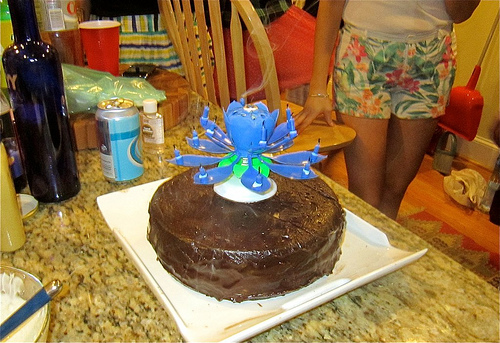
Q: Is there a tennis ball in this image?
A: No, there are no tennis balls.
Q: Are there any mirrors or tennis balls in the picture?
A: No, there are no tennis balls or mirrors.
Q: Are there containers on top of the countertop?
A: Yes, there is a container on top of the countertop.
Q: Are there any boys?
A: No, there are no boys.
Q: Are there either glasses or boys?
A: No, there are no boys or glasses.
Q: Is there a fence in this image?
A: No, there are no fences.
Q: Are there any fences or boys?
A: No, there are no fences or boys.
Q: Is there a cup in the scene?
A: Yes, there is a cup.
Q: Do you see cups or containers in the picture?
A: Yes, there is a cup.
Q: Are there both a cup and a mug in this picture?
A: No, there is a cup but no mugs.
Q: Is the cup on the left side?
A: Yes, the cup is on the left of the image.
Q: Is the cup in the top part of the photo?
A: Yes, the cup is in the top of the image.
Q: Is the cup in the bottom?
A: No, the cup is in the top of the image.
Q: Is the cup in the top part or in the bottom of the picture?
A: The cup is in the top of the image.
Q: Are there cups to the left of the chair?
A: Yes, there is a cup to the left of the chair.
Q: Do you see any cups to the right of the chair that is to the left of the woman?
A: No, the cup is to the left of the chair.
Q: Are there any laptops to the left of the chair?
A: No, there is a cup to the left of the chair.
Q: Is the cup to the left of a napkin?
A: No, the cup is to the left of a chair.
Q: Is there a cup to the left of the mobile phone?
A: Yes, there is a cup to the left of the mobile phone.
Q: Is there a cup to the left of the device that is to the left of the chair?
A: Yes, there is a cup to the left of the mobile phone.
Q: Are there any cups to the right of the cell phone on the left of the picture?
A: No, the cup is to the left of the cell phone.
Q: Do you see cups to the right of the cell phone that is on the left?
A: No, the cup is to the left of the cell phone.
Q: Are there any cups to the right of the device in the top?
A: No, the cup is to the left of the cell phone.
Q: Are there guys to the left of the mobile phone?
A: No, there is a cup to the left of the mobile phone.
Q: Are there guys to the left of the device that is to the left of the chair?
A: No, there is a cup to the left of the mobile phone.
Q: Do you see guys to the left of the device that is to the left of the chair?
A: No, there is a cup to the left of the mobile phone.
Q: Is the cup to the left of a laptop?
A: No, the cup is to the left of a cell phone.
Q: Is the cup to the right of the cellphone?
A: No, the cup is to the left of the cellphone.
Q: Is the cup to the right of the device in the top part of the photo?
A: No, the cup is to the left of the cellphone.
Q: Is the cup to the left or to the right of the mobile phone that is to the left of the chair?
A: The cup is to the left of the cell phone.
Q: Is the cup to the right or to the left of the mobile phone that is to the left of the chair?
A: The cup is to the left of the cell phone.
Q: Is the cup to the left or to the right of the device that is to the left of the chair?
A: The cup is to the left of the cell phone.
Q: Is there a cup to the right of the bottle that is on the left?
A: Yes, there is a cup to the right of the bottle.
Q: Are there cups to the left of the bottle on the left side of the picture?
A: No, the cup is to the right of the bottle.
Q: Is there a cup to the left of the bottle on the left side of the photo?
A: No, the cup is to the right of the bottle.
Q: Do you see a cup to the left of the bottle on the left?
A: No, the cup is to the right of the bottle.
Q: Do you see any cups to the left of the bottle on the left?
A: No, the cup is to the right of the bottle.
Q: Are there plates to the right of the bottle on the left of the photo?
A: No, there is a cup to the right of the bottle.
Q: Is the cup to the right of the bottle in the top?
A: Yes, the cup is to the right of the bottle.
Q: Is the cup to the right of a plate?
A: No, the cup is to the right of the bottle.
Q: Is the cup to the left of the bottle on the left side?
A: No, the cup is to the right of the bottle.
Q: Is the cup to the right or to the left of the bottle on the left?
A: The cup is to the right of the bottle.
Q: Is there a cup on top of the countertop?
A: Yes, there is a cup on top of the countertop.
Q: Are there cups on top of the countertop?
A: Yes, there is a cup on top of the countertop.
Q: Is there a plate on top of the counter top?
A: No, there is a cup on top of the counter top.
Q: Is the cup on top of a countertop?
A: Yes, the cup is on top of a countertop.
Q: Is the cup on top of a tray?
A: No, the cup is on top of a countertop.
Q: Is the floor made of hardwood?
A: Yes, the floor is made of hardwood.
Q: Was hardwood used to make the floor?
A: Yes, the floor is made of hardwood.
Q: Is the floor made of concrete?
A: No, the floor is made of hardwood.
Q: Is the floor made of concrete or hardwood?
A: The floor is made of hardwood.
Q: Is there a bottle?
A: Yes, there is a bottle.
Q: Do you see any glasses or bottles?
A: Yes, there is a bottle.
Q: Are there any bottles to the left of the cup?
A: Yes, there is a bottle to the left of the cup.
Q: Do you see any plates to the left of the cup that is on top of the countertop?
A: No, there is a bottle to the left of the cup.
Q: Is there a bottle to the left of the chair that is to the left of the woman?
A: Yes, there is a bottle to the left of the chair.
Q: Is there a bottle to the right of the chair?
A: No, the bottle is to the left of the chair.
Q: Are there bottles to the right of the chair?
A: No, the bottle is to the left of the chair.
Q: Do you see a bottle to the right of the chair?
A: No, the bottle is to the left of the chair.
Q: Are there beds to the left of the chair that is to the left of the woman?
A: No, there is a bottle to the left of the chair.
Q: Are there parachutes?
A: No, there are no parachutes.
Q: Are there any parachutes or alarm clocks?
A: No, there are no parachutes or alarm clocks.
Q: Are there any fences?
A: No, there are no fences.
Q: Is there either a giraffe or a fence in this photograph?
A: No, there are no fences or giraffes.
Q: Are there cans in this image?
A: Yes, there is a can.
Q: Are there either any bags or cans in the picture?
A: Yes, there is a can.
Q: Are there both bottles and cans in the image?
A: Yes, there are both a can and a bottle.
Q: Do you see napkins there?
A: No, there are no napkins.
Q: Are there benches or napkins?
A: No, there are no napkins or benches.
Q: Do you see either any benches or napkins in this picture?
A: No, there are no napkins or benches.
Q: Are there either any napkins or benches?
A: No, there are no napkins or benches.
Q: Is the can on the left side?
A: Yes, the can is on the left of the image.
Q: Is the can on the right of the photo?
A: No, the can is on the left of the image.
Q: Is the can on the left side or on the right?
A: The can is on the left of the image.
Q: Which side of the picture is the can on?
A: The can is on the left of the image.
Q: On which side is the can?
A: The can is on the left of the image.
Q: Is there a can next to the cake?
A: Yes, there is a can next to the cake.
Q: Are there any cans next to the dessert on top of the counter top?
A: Yes, there is a can next to the cake.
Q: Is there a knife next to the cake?
A: No, there is a can next to the cake.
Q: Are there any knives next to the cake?
A: No, there is a can next to the cake.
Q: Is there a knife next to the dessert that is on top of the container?
A: No, there is a can next to the cake.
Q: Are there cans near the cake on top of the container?
A: Yes, there is a can near the cake.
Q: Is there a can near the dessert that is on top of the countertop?
A: Yes, there is a can near the cake.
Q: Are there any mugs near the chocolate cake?
A: No, there is a can near the cake.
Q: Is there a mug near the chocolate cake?
A: No, there is a can near the cake.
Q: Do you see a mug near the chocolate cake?
A: No, there is a can near the cake.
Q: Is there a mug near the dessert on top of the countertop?
A: No, there is a can near the cake.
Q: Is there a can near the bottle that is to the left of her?
A: Yes, there is a can near the bottle.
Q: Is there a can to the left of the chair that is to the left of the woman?
A: Yes, there is a can to the left of the chair.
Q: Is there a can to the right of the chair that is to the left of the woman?
A: No, the can is to the left of the chair.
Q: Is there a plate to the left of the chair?
A: No, there is a can to the left of the chair.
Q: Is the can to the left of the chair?
A: Yes, the can is to the left of the chair.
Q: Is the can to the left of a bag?
A: No, the can is to the left of the chair.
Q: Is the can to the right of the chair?
A: No, the can is to the left of the chair.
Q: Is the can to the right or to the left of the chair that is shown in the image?
A: The can is to the left of the chair.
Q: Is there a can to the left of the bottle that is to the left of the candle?
A: Yes, there is a can to the left of the bottle.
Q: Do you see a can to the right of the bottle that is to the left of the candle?
A: No, the can is to the left of the bottle.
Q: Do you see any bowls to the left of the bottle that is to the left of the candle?
A: No, there is a can to the left of the bottle.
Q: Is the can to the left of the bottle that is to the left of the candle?
A: Yes, the can is to the left of the bottle.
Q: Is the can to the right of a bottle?
A: No, the can is to the left of a bottle.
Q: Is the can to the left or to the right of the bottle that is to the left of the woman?
A: The can is to the left of the bottle.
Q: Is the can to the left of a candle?
A: Yes, the can is to the left of a candle.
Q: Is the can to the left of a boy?
A: No, the can is to the left of a candle.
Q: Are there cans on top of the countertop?
A: Yes, there is a can on top of the countertop.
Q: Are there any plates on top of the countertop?
A: No, there is a can on top of the countertop.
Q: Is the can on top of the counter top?
A: Yes, the can is on top of the counter top.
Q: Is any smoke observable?
A: Yes, there is smoke.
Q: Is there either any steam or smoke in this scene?
A: Yes, there is smoke.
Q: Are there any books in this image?
A: No, there are no books.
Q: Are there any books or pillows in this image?
A: No, there are no books or pillows.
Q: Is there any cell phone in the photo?
A: Yes, there is a cell phone.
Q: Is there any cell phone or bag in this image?
A: Yes, there is a cell phone.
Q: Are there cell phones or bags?
A: Yes, there is a cell phone.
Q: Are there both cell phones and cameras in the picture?
A: No, there is a cell phone but no cameras.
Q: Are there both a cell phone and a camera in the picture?
A: No, there is a cell phone but no cameras.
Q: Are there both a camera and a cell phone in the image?
A: No, there is a cell phone but no cameras.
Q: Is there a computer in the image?
A: No, there are no computers.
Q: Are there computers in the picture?
A: No, there are no computers.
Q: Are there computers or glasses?
A: No, there are no computers or glasses.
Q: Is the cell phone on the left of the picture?
A: Yes, the cell phone is on the left of the image.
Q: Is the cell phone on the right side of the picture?
A: No, the cell phone is on the left of the image.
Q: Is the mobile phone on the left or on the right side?
A: The mobile phone is on the left of the image.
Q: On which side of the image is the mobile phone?
A: The mobile phone is on the left of the image.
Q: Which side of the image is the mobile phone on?
A: The mobile phone is on the left of the image.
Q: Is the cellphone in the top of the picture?
A: Yes, the cellphone is in the top of the image.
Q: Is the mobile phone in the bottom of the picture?
A: No, the mobile phone is in the top of the image.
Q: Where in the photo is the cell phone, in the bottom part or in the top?
A: The cell phone is in the top of the image.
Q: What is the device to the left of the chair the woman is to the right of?
A: The device is a cell phone.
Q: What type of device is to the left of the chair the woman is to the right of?
A: The device is a cell phone.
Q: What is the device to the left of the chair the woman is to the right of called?
A: The device is a cell phone.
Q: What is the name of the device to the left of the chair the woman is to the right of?
A: The device is a cell phone.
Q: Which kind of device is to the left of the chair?
A: The device is a cell phone.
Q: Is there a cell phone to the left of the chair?
A: Yes, there is a cell phone to the left of the chair.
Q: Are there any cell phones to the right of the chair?
A: No, the cell phone is to the left of the chair.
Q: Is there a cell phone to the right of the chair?
A: No, the cell phone is to the left of the chair.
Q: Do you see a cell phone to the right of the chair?
A: No, the cell phone is to the left of the chair.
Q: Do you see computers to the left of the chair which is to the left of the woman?
A: No, there is a cell phone to the left of the chair.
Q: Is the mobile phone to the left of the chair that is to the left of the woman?
A: Yes, the mobile phone is to the left of the chair.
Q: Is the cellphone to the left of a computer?
A: No, the cellphone is to the left of the chair.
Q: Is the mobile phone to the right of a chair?
A: No, the mobile phone is to the left of a chair.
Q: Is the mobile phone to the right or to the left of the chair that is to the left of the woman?
A: The mobile phone is to the left of the chair.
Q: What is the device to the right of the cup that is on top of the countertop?
A: The device is a cell phone.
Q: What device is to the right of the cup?
A: The device is a cell phone.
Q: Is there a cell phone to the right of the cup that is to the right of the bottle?
A: Yes, there is a cell phone to the right of the cup.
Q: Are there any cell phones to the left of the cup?
A: No, the cell phone is to the right of the cup.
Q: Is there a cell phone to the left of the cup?
A: No, the cell phone is to the right of the cup.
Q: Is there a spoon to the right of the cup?
A: No, there is a cell phone to the right of the cup.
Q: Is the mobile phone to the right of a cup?
A: Yes, the mobile phone is to the right of a cup.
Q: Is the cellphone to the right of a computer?
A: No, the cellphone is to the right of a cup.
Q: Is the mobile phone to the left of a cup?
A: No, the mobile phone is to the right of a cup.